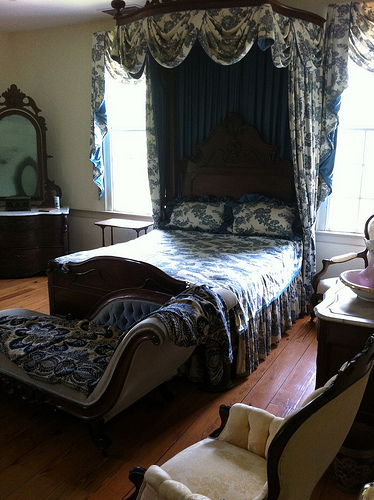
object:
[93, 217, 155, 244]
side table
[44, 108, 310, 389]
bed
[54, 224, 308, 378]
cover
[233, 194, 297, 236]
pillow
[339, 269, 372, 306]
bowl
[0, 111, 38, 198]
mirror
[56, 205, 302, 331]
bedspread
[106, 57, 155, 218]
window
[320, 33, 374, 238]
window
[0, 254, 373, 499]
ground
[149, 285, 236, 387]
blanket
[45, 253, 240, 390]
bottom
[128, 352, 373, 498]
chair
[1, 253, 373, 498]
floor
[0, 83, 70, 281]
vanity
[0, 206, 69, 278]
dresser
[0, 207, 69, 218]
white counter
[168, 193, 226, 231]
pillow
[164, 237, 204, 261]
fabric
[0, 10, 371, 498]
bedroom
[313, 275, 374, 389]
table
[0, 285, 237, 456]
chair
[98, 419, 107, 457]
wooden stand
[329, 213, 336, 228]
sunlight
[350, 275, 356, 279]
pitcher